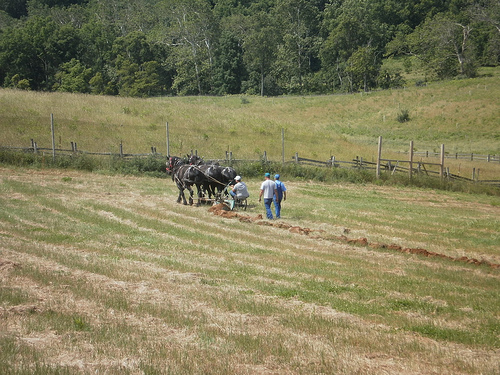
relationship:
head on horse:
[166, 155, 180, 175] [161, 152, 217, 207]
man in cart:
[229, 175, 250, 203] [197, 191, 244, 208]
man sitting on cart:
[228, 175, 250, 205] [205, 182, 249, 214]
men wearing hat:
[255, 167, 288, 222] [264, 173, 270, 178]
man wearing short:
[218, 160, 334, 251] [248, 192, 275, 216]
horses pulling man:
[165, 149, 237, 206] [226, 170, 258, 209]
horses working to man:
[165, 149, 237, 206] [273, 172, 288, 219]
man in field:
[258, 170, 272, 218] [2, 160, 496, 372]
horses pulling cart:
[159, 147, 237, 209] [205, 182, 249, 214]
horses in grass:
[159, 147, 237, 209] [1, 79, 499, 372]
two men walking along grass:
[260, 167, 289, 222] [2, 146, 492, 371]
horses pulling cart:
[165, 149, 237, 206] [181, 140, 242, 201]